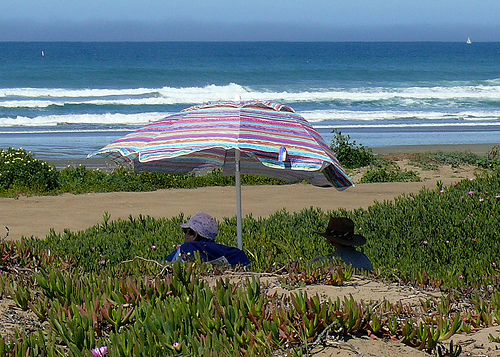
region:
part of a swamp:
[388, 226, 416, 256]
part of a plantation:
[236, 325, 251, 342]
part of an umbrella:
[244, 125, 266, 137]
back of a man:
[342, 256, 343, 276]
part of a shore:
[86, 161, 115, 191]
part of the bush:
[15, 152, 35, 182]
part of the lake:
[383, 122, 400, 156]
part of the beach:
[380, 123, 387, 131]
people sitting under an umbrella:
[80, 93, 375, 270]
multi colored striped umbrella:
[78, 87, 365, 193]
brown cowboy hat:
[312, 208, 371, 245]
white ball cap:
[175, 207, 219, 241]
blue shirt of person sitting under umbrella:
[166, 238, 255, 265]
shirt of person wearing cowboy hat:
[307, 251, 379, 278]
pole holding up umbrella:
[229, 149, 258, 254]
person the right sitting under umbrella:
[305, 206, 379, 277]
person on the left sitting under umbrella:
[149, 207, 259, 268]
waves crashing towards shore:
[1, 78, 498, 123]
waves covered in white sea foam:
[164, 79, 253, 100]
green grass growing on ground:
[409, 198, 460, 237]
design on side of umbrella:
[149, 110, 297, 145]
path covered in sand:
[0, 183, 137, 254]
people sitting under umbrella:
[143, 188, 400, 305]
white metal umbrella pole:
[229, 155, 254, 250]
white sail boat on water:
[441, 31, 491, 54]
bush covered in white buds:
[0, 139, 62, 194]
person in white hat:
[178, 212, 230, 265]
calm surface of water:
[120, 38, 380, 77]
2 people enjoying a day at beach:
[157, 197, 384, 275]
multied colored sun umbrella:
[90, 88, 363, 222]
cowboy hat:
[317, 215, 372, 250]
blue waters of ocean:
[5, 36, 489, 133]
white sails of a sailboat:
[452, 34, 476, 46]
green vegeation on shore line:
[4, 142, 182, 198]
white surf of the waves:
[327, 89, 492, 126]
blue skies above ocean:
[7, 10, 495, 43]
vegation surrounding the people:
[25, 205, 495, 345]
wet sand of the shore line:
[357, 123, 496, 150]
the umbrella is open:
[78, 75, 366, 193]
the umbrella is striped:
[90, 93, 361, 190]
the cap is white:
[174, 211, 226, 244]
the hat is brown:
[306, 215, 374, 250]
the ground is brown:
[37, 195, 186, 209]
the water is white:
[154, 83, 237, 101]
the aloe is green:
[215, 283, 368, 328]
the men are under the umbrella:
[107, 75, 406, 273]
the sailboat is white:
[450, 30, 477, 49]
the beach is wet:
[49, 136, 85, 158]